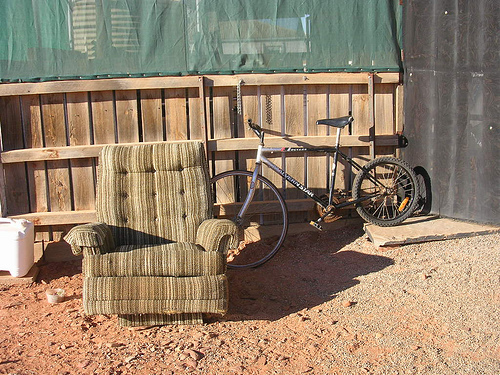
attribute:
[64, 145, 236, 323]
chair — striped, yellow, couch, empty, short, old, livingroom, shabby, green, stripped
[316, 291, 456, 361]
dirt — red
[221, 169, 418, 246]
wheels — front bike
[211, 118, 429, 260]
bicycle — gray, black, parked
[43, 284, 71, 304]
bowl — small, plastci, empty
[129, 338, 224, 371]
rocks — red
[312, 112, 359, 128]
seat — black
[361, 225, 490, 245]
concrete slab — small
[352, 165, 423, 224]
bicycle tire — rear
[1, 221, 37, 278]
jug — white, empty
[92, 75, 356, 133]
fence — wooden, outdoor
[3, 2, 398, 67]
screen — green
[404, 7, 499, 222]
tarp — black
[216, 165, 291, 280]
front tyre — big